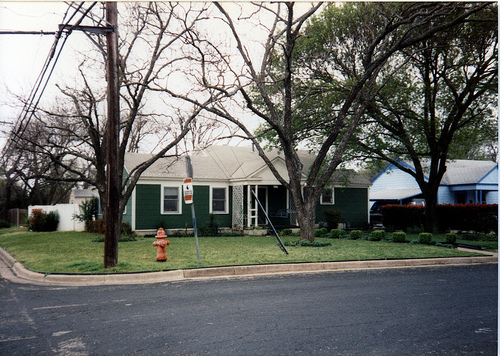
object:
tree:
[0, 0, 258, 270]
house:
[366, 155, 498, 226]